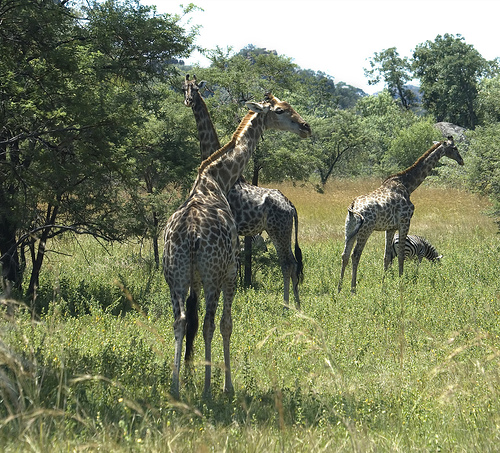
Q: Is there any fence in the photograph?
A: No, there are no fences.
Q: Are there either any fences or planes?
A: No, there are no fences or planes.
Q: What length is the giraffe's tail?
A: The tail is long.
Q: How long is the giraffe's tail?
A: The tail is long.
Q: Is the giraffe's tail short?
A: No, the tail is long.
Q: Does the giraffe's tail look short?
A: No, the tail is long.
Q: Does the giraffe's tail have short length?
A: No, the tail is long.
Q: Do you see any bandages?
A: No, there are no bandages.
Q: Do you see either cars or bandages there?
A: No, there are no bandages or cars.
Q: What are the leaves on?
A: The leaves are on the trees.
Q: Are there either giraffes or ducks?
A: Yes, there is a giraffe.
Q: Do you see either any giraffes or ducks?
A: Yes, there is a giraffe.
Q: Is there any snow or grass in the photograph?
A: Yes, there is grass.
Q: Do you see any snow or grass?
A: Yes, there is grass.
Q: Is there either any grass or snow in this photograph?
A: Yes, there is grass.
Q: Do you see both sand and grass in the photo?
A: No, there is grass but no sand.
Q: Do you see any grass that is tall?
A: Yes, there is tall grass.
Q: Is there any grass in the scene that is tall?
A: Yes, there is tall grass.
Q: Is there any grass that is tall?
A: Yes, there is grass that is tall.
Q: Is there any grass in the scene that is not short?
A: Yes, there is tall grass.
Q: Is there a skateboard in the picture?
A: No, there are no skateboards.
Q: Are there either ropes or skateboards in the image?
A: No, there are no skateboards or ropes.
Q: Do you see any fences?
A: No, there are no fences.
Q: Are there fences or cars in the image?
A: No, there are no fences or cars.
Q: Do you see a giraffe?
A: Yes, there is a giraffe.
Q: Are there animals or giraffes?
A: Yes, there is a giraffe.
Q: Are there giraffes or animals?
A: Yes, there is a giraffe.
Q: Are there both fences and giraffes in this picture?
A: No, there is a giraffe but no fences.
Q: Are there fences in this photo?
A: No, there are no fences.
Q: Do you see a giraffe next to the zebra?
A: Yes, there is a giraffe next to the zebra.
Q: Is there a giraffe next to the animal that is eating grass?
A: Yes, there is a giraffe next to the zebra.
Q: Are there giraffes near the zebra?
A: Yes, there is a giraffe near the zebra.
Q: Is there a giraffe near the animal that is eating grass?
A: Yes, there is a giraffe near the zebra.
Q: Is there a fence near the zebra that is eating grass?
A: No, there is a giraffe near the zebra.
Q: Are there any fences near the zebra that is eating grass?
A: No, there is a giraffe near the zebra.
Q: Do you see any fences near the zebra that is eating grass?
A: No, there is a giraffe near the zebra.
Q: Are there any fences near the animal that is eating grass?
A: No, there is a giraffe near the zebra.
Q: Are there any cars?
A: No, there are no cars.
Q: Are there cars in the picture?
A: No, there are no cars.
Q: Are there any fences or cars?
A: No, there are no cars or fences.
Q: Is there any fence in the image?
A: No, there are no fences.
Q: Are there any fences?
A: No, there are no fences.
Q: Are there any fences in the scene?
A: No, there are no fences.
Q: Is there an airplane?
A: No, there are no airplanes.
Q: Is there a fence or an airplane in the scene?
A: No, there are no airplanes or fences.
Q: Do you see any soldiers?
A: No, there are no soldiers.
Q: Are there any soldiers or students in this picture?
A: No, there are no soldiers or students.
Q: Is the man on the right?
A: Yes, the man is on the right of the image.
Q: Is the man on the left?
A: No, the man is on the right of the image.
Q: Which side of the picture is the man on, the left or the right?
A: The man is on the right of the image.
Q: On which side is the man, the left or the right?
A: The man is on the right of the image.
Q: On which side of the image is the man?
A: The man is on the right of the image.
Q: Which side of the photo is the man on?
A: The man is on the right of the image.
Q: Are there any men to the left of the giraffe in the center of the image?
A: No, the man is to the right of the giraffe.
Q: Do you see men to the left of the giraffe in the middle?
A: No, the man is to the right of the giraffe.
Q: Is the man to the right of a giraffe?
A: Yes, the man is to the right of a giraffe.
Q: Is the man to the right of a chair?
A: No, the man is to the right of a giraffe.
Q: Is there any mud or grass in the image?
A: Yes, there is grass.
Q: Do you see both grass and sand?
A: No, there is grass but no sand.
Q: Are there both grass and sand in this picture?
A: No, there is grass but no sand.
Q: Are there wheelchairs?
A: No, there are no wheelchairs.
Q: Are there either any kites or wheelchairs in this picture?
A: No, there are no wheelchairs or kites.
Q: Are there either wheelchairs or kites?
A: No, there are no wheelchairs or kites.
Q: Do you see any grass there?
A: Yes, there is grass.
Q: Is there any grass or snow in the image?
A: Yes, there is grass.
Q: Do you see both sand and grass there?
A: No, there is grass but no sand.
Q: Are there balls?
A: No, there are no balls.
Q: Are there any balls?
A: No, there are no balls.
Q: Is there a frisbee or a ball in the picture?
A: No, there are no balls or frisbees.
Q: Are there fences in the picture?
A: No, there are no fences.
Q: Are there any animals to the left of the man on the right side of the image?
A: Yes, there is an animal to the left of the man.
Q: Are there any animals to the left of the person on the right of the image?
A: Yes, there is an animal to the left of the man.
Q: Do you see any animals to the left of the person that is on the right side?
A: Yes, there is an animal to the left of the man.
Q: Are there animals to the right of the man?
A: No, the animal is to the left of the man.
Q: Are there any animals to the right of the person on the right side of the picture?
A: No, the animal is to the left of the man.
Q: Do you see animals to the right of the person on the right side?
A: No, the animal is to the left of the man.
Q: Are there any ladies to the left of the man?
A: No, there is an animal to the left of the man.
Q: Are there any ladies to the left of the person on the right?
A: No, there is an animal to the left of the man.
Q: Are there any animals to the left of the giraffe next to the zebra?
A: Yes, there is an animal to the left of the giraffe.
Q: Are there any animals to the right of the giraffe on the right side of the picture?
A: No, the animal is to the left of the giraffe.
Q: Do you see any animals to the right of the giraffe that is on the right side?
A: No, the animal is to the left of the giraffe.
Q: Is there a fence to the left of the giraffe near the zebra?
A: No, there is an animal to the left of the giraffe.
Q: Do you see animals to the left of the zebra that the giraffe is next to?
A: Yes, there is an animal to the left of the zebra.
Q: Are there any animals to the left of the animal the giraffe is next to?
A: Yes, there is an animal to the left of the zebra.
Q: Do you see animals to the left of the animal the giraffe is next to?
A: Yes, there is an animal to the left of the zebra.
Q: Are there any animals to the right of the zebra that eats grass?
A: No, the animal is to the left of the zebra.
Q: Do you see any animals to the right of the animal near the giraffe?
A: No, the animal is to the left of the zebra.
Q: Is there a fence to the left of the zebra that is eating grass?
A: No, there is an animal to the left of the zebra.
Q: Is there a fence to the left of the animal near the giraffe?
A: No, there is an animal to the left of the zebra.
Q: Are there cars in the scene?
A: No, there are no cars.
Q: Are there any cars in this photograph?
A: No, there are no cars.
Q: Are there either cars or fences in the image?
A: No, there are no cars or fences.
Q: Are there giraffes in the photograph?
A: Yes, there is a giraffe.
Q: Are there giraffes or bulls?
A: Yes, there is a giraffe.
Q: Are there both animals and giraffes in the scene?
A: Yes, there are both a giraffe and an animal.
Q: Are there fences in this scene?
A: No, there are no fences.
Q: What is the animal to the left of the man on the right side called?
A: The animal is a giraffe.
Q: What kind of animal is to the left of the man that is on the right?
A: The animal is a giraffe.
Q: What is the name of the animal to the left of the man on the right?
A: The animal is a giraffe.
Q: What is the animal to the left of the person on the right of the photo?
A: The animal is a giraffe.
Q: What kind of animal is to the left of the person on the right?
A: The animal is a giraffe.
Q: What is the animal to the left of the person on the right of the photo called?
A: The animal is a giraffe.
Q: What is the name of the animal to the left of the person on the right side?
A: The animal is a giraffe.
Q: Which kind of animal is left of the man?
A: The animal is a giraffe.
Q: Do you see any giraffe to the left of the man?
A: Yes, there is a giraffe to the left of the man.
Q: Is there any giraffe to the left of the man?
A: Yes, there is a giraffe to the left of the man.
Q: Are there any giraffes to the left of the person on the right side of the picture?
A: Yes, there is a giraffe to the left of the man.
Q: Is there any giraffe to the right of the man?
A: No, the giraffe is to the left of the man.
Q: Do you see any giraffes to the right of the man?
A: No, the giraffe is to the left of the man.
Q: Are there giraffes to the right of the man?
A: No, the giraffe is to the left of the man.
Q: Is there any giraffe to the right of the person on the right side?
A: No, the giraffe is to the left of the man.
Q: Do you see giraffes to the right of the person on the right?
A: No, the giraffe is to the left of the man.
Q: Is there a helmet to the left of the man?
A: No, there is a giraffe to the left of the man.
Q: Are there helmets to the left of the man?
A: No, there is a giraffe to the left of the man.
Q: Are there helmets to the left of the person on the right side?
A: No, there is a giraffe to the left of the man.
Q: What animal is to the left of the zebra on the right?
A: The animal is a giraffe.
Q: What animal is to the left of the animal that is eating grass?
A: The animal is a giraffe.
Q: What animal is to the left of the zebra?
A: The animal is a giraffe.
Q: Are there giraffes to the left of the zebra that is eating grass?
A: Yes, there is a giraffe to the left of the zebra.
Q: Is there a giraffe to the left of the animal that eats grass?
A: Yes, there is a giraffe to the left of the zebra.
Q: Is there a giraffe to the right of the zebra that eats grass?
A: No, the giraffe is to the left of the zebra.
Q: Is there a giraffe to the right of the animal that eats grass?
A: No, the giraffe is to the left of the zebra.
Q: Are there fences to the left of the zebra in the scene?
A: No, there is a giraffe to the left of the zebra.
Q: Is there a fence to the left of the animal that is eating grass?
A: No, there is a giraffe to the left of the zebra.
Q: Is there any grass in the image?
A: Yes, there is grass.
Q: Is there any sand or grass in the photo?
A: Yes, there is grass.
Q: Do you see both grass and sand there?
A: No, there is grass but no sand.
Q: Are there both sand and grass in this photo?
A: No, there is grass but no sand.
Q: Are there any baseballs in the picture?
A: No, there are no baseballs.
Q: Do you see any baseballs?
A: No, there are no baseballs.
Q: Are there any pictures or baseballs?
A: No, there are no baseballs or pictures.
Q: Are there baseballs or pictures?
A: No, there are no baseballs or pictures.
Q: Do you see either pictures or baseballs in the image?
A: No, there are no baseballs or pictures.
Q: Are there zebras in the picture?
A: Yes, there is a zebra.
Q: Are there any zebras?
A: Yes, there is a zebra.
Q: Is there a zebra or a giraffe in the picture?
A: Yes, there is a zebra.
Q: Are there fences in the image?
A: No, there are no fences.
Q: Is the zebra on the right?
A: Yes, the zebra is on the right of the image.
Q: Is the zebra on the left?
A: No, the zebra is on the right of the image.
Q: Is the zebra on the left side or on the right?
A: The zebra is on the right of the image.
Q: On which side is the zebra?
A: The zebra is on the right of the image.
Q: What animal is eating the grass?
A: The zebra is eating the grass.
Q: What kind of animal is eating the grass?
A: The animal is a zebra.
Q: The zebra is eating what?
A: The zebra is eating grass.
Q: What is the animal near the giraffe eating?
A: The zebra is eating grass.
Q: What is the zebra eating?
A: The zebra is eating grass.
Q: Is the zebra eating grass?
A: Yes, the zebra is eating grass.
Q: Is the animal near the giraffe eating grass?
A: Yes, the zebra is eating grass.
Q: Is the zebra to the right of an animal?
A: Yes, the zebra is to the right of an animal.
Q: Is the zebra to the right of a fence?
A: No, the zebra is to the right of an animal.